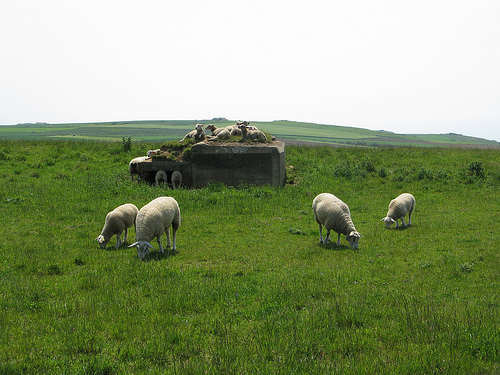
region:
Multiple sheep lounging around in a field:
[25, 89, 467, 336]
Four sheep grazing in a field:
[65, 186, 440, 286]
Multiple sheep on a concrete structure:
[187, 108, 286, 158]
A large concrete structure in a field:
[100, 139, 281, 191]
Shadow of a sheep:
[140, 245, 185, 265]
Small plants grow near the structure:
[334, 145, 479, 180]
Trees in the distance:
[272, 115, 378, 135]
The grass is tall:
[147, 277, 397, 364]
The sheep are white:
[102, 191, 174, 258]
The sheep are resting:
[187, 119, 271, 148]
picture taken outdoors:
[63, 27, 486, 291]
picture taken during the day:
[52, 70, 458, 340]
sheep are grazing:
[68, 175, 438, 275]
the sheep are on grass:
[83, 181, 498, 297]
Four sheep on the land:
[85, 175, 495, 270]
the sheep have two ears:
[90, 199, 261, 281]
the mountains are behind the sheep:
[84, 111, 495, 213]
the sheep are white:
[95, 180, 463, 292]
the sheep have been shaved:
[98, 184, 494, 328]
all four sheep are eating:
[54, 195, 484, 293]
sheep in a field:
[54, 57, 494, 330]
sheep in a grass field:
[41, 56, 493, 346]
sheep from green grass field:
[78, 54, 457, 327]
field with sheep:
[46, 70, 476, 373]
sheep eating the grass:
[34, 72, 455, 328]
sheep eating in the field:
[65, 67, 496, 314]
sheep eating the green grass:
[47, 70, 489, 366]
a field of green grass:
[193, 209, 425, 354]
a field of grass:
[179, 260, 411, 372]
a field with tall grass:
[177, 264, 398, 371]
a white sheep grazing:
[131, 192, 179, 258]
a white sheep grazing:
[97, 204, 135, 249]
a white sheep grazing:
[309, 194, 360, 251]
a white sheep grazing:
[382, 192, 414, 229]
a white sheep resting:
[180, 124, 205, 142]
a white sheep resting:
[204, 121, 229, 139]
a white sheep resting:
[236, 122, 264, 142]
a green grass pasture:
[2, 139, 497, 371]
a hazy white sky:
[0, 4, 499, 136]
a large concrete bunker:
[129, 140, 287, 189]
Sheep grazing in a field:
[106, 105, 458, 322]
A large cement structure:
[134, 145, 287, 197]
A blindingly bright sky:
[185, 46, 380, 120]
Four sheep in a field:
[62, 182, 453, 292]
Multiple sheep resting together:
[177, 117, 272, 146]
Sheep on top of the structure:
[171, 103, 291, 203]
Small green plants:
[324, 150, 457, 185]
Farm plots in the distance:
[15, 120, 172, 140]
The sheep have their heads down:
[89, 200, 192, 266]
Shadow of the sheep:
[135, 247, 177, 268]